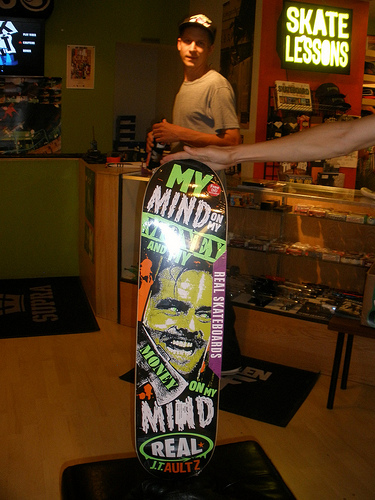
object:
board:
[156, 172, 222, 398]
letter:
[173, 434, 189, 458]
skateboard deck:
[131, 163, 243, 490]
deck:
[15, 336, 342, 486]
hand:
[158, 147, 228, 172]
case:
[237, 193, 360, 323]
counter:
[241, 180, 363, 325]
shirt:
[171, 68, 240, 148]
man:
[141, 7, 244, 387]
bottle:
[147, 130, 166, 171]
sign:
[287, 2, 348, 74]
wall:
[258, 8, 355, 121]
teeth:
[166, 343, 193, 355]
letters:
[25, 280, 69, 329]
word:
[139, 395, 213, 433]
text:
[143, 408, 209, 422]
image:
[145, 253, 208, 381]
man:
[170, 115, 363, 211]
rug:
[225, 352, 293, 424]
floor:
[48, 346, 341, 450]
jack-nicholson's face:
[142, 253, 212, 379]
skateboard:
[132, 155, 224, 484]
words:
[142, 162, 228, 433]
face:
[177, 37, 206, 69]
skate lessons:
[286, 4, 351, 66]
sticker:
[201, 180, 219, 200]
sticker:
[136, 427, 211, 468]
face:
[144, 262, 214, 377]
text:
[204, 266, 230, 359]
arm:
[157, 113, 372, 175]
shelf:
[114, 112, 135, 131]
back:
[4, 24, 165, 280]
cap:
[173, 10, 220, 44]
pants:
[221, 289, 244, 372]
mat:
[0, 272, 103, 340]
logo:
[1, 280, 64, 329]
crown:
[2, 287, 29, 318]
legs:
[320, 330, 358, 411]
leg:
[335, 334, 355, 391]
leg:
[321, 330, 346, 410]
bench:
[315, 311, 372, 413]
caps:
[315, 79, 350, 114]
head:
[174, 13, 218, 72]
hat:
[173, 13, 220, 45]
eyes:
[179, 34, 209, 50]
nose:
[185, 37, 201, 56]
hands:
[141, 114, 170, 156]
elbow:
[216, 131, 239, 147]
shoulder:
[199, 69, 233, 104]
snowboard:
[133, 155, 227, 474]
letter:
[150, 440, 166, 456]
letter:
[178, 439, 190, 456]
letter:
[159, 435, 182, 460]